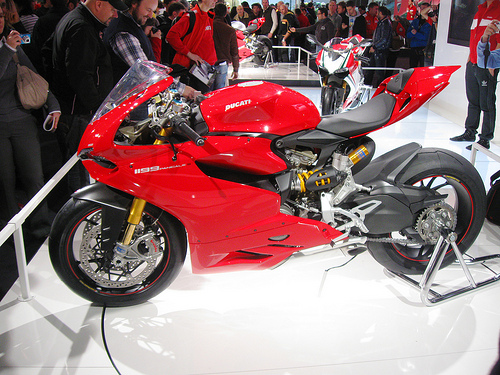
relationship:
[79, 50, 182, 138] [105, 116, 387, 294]
window of motorbike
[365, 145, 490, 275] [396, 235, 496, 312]
tire on stand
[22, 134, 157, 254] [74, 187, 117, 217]
light reflection on fender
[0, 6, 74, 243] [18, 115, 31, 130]
woman holding phone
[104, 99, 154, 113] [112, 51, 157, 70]
sleeve of shirt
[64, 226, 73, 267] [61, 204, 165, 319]
outline on rubber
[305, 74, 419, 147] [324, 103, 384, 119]
surface of seat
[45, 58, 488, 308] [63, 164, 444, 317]
motorbike has wheels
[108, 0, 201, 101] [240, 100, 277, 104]
men in a jacket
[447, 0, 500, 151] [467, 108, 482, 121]
man in a jacket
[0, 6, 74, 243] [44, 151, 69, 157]
woman in green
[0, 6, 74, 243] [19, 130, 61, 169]
woman holding camera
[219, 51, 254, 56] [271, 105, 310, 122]
person in a jacket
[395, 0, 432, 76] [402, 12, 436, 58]
person wearing shirt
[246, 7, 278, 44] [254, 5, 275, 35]
person wearing vest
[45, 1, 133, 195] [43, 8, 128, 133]
man wearing a shirt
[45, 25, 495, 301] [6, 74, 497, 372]
motorbike on racks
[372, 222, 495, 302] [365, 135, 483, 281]
rack holding tire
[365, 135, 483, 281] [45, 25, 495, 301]
tire from motorbike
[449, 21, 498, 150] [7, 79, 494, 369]
man standing on stage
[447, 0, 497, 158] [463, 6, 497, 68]
man wearing shirt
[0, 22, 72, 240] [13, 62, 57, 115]
woman holding handbag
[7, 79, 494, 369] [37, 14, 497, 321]
stage on bike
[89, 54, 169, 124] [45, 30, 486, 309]
windshield in front of bike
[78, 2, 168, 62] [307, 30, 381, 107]
men are looking at motorcycle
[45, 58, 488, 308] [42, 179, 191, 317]
motorbike has wheel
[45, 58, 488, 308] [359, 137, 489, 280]
motorbike has wheel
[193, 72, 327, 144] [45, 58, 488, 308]
gas tank on motorbike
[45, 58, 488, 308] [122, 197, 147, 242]
motorbike has shock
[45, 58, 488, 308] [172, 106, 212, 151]
motorbike has handle bar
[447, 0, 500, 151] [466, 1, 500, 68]
man wears shirt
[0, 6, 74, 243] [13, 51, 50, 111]
woman carry handbag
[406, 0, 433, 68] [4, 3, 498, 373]
person at exhibit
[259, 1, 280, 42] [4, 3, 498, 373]
person at exhibit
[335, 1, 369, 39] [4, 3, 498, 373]
person at exhibit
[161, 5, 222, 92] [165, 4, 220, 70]
man wearing sweater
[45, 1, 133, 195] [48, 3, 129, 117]
man wearing shirt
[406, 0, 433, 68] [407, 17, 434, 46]
person wearing jacket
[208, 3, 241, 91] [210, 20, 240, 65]
person wearing jacket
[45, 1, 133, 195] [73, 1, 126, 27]
man has head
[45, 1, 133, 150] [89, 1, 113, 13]
man has ear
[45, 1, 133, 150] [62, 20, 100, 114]
man has arm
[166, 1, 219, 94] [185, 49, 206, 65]
man has hand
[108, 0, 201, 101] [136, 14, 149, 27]
men has chin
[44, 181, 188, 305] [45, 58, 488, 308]
wheel on motorbike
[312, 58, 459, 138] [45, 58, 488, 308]
seat on motorbike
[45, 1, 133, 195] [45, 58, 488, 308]
man next to motorbike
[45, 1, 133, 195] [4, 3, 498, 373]
man at exhibit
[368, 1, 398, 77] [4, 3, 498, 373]
person at exhibit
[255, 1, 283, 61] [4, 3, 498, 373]
person in exhibit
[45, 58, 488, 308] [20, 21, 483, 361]
motorbike on display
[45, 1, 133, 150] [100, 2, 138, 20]
man wearing baseball cap